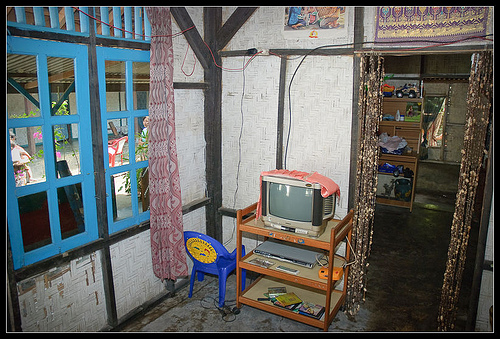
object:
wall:
[219, 54, 349, 209]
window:
[1, 38, 100, 270]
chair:
[184, 230, 246, 306]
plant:
[11, 100, 67, 167]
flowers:
[56, 152, 62, 158]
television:
[261, 174, 335, 238]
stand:
[237, 203, 354, 331]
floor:
[119, 232, 453, 335]